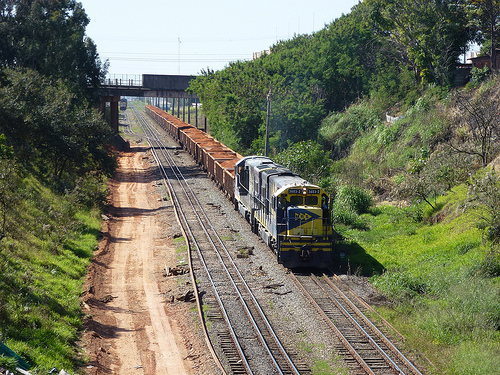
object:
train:
[233, 155, 334, 269]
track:
[131, 102, 301, 373]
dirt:
[86, 143, 185, 374]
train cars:
[144, 101, 248, 198]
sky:
[96, 1, 361, 73]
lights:
[302, 191, 306, 195]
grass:
[1, 134, 106, 372]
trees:
[1, 0, 110, 187]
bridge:
[92, 74, 207, 98]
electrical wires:
[99, 48, 249, 63]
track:
[299, 274, 402, 373]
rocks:
[278, 303, 284, 308]